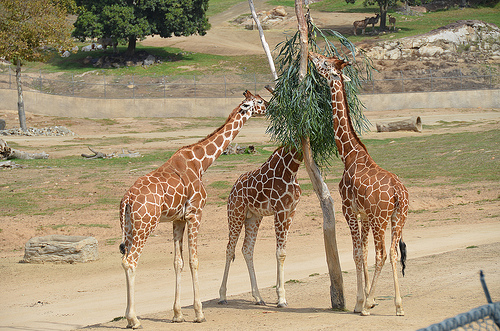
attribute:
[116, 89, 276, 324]
giraffes — white, brown, tan, part, eating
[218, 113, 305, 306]
giraffes — spotted, tan, eating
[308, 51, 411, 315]
giraffes — tall, eating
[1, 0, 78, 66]
leaves — green, yellow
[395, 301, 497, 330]
fence — part, silver, lower right, edge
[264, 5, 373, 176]
limb — green, hanging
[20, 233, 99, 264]
rock — edge, square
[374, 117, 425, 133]
pipe — dead, oblong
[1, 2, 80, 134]
tree — edge, skinny, small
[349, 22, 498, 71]
hill — rocky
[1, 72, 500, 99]
fence — metal, long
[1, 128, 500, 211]
grass — brown, green, short, part